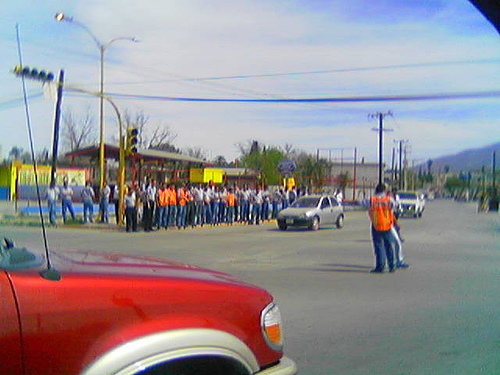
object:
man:
[370, 178, 398, 282]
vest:
[367, 193, 395, 232]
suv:
[2, 233, 300, 375]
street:
[1, 194, 495, 375]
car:
[276, 194, 346, 230]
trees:
[226, 145, 500, 197]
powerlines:
[0, 47, 423, 113]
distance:
[217, 107, 496, 211]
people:
[117, 182, 300, 234]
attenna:
[14, 21, 60, 279]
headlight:
[52, 12, 67, 25]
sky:
[0, 0, 497, 184]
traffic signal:
[14, 67, 138, 229]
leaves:
[220, 140, 499, 193]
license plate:
[280, 215, 299, 225]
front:
[277, 205, 315, 232]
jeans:
[373, 226, 396, 277]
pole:
[377, 108, 387, 197]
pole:
[51, 10, 142, 229]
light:
[51, 12, 150, 50]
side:
[18, 193, 253, 237]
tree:
[52, 97, 181, 166]